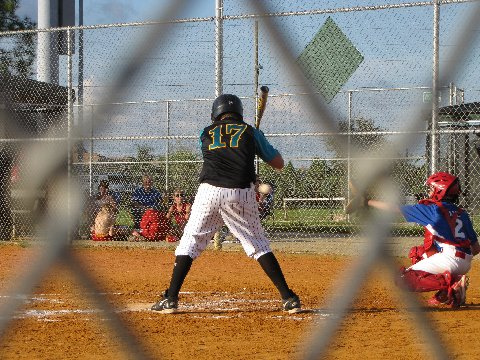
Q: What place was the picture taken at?
A: It was taken at the field.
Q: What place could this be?
A: It is a field.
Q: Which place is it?
A: It is a field.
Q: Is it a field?
A: Yes, it is a field.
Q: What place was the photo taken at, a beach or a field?
A: It was taken at a field.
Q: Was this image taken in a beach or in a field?
A: It was taken at a field.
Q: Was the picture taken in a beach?
A: No, the picture was taken in a field.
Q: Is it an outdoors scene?
A: Yes, it is outdoors.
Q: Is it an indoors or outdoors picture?
A: It is outdoors.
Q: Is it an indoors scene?
A: No, it is outdoors.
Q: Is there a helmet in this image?
A: Yes, there is a helmet.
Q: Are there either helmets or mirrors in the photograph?
A: Yes, there is a helmet.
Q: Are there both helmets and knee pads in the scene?
A: No, there is a helmet but no knee pads.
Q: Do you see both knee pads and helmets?
A: No, there is a helmet but no knee pads.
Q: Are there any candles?
A: No, there are no candles.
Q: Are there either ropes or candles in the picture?
A: No, there are no candles or ropes.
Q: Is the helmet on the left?
A: No, the helmet is on the right of the image.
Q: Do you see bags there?
A: No, there are no bags.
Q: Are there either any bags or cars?
A: No, there are no bags or cars.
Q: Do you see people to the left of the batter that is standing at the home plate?
A: Yes, there is a person to the left of the batter.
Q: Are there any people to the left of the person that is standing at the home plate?
A: Yes, there is a person to the left of the batter.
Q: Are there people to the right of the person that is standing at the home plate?
A: No, the person is to the left of the batter.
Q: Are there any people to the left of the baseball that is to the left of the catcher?
A: Yes, there is a person to the left of the baseball.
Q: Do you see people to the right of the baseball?
A: No, the person is to the left of the baseball.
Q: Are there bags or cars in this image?
A: No, there are no cars or bags.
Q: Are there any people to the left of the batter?
A: Yes, there is a person to the left of the batter.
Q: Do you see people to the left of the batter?
A: Yes, there is a person to the left of the batter.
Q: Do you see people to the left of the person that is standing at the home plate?
A: Yes, there is a person to the left of the batter.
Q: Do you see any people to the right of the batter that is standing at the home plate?
A: No, the person is to the left of the batter.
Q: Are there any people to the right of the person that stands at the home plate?
A: No, the person is to the left of the batter.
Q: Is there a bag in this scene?
A: No, there are no bags.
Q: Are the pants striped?
A: Yes, the pants are striped.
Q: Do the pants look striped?
A: Yes, the pants are striped.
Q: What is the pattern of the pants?
A: The pants are striped.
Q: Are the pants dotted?
A: No, the pants are striped.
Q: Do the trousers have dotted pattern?
A: No, the trousers are striped.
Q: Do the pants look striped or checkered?
A: The pants are striped.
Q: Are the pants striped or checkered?
A: The pants are striped.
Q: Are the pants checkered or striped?
A: The pants are striped.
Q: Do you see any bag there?
A: No, there are no bags.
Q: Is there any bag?
A: No, there are no bags.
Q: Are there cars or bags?
A: No, there are no bags or cars.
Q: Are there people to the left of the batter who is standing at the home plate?
A: Yes, there is a person to the left of the batter.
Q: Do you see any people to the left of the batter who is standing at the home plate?
A: Yes, there is a person to the left of the batter.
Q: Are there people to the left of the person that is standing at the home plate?
A: Yes, there is a person to the left of the batter.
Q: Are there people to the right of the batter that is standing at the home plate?
A: No, the person is to the left of the batter.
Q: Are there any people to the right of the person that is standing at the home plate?
A: No, the person is to the left of the batter.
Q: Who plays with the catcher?
A: The batter plays with the catcher.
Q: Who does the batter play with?
A: The batter plays with the catcher.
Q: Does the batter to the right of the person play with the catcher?
A: Yes, the batter plays with the catcher.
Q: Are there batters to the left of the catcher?
A: Yes, there is a batter to the left of the catcher.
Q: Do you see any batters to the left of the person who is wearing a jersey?
A: Yes, there is a batter to the left of the catcher.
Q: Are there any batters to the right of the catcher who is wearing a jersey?
A: No, the batter is to the left of the catcher.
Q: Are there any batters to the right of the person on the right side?
A: No, the batter is to the left of the catcher.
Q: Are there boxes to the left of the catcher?
A: No, there is a batter to the left of the catcher.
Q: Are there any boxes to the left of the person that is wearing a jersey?
A: No, there is a batter to the left of the catcher.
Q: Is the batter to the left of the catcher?
A: Yes, the batter is to the left of the catcher.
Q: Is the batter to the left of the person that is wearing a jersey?
A: Yes, the batter is to the left of the catcher.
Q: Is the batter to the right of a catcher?
A: No, the batter is to the left of a catcher.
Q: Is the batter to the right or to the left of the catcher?
A: The batter is to the left of the catcher.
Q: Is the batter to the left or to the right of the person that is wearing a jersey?
A: The batter is to the left of the catcher.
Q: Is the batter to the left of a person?
A: No, the batter is to the right of a person.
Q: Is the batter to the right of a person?
A: Yes, the batter is to the right of a person.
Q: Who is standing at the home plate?
A: The batter is standing at the home plate.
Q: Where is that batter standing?
A: The batter is standing at the home plate.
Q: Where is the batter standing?
A: The batter is standing at the home plate.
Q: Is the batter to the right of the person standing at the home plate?
A: Yes, the batter is standing at the home plate.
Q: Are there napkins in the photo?
A: No, there are no napkins.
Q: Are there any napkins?
A: No, there are no napkins.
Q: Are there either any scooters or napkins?
A: No, there are no napkins or scooters.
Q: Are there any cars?
A: No, there are no cars.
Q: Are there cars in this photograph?
A: No, there are no cars.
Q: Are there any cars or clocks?
A: No, there are no cars or clocks.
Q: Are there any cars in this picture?
A: No, there are no cars.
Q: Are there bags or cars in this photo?
A: No, there are no cars or bags.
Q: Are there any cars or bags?
A: No, there are no cars or bags.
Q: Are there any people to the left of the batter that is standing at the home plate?
A: Yes, there is a person to the left of the batter.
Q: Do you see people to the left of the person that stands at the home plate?
A: Yes, there is a person to the left of the batter.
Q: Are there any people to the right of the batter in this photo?
A: No, the person is to the left of the batter.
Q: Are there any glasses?
A: No, there are no glasses.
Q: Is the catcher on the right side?
A: Yes, the catcher is on the right of the image.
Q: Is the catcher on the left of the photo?
A: No, the catcher is on the right of the image.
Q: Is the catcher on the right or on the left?
A: The catcher is on the right of the image.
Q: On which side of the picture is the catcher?
A: The catcher is on the right of the image.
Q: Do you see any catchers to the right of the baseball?
A: Yes, there is a catcher to the right of the baseball.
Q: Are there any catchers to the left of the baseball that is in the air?
A: No, the catcher is to the right of the baseball.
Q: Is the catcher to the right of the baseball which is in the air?
A: Yes, the catcher is to the right of the baseball.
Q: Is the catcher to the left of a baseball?
A: No, the catcher is to the right of a baseball.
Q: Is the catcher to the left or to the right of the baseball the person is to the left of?
A: The catcher is to the right of the baseball.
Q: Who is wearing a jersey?
A: The catcher is wearing a jersey.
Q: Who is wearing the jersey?
A: The catcher is wearing a jersey.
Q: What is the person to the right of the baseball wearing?
A: The catcher is wearing a jersey.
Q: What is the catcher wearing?
A: The catcher is wearing a jersey.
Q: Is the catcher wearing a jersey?
A: Yes, the catcher is wearing a jersey.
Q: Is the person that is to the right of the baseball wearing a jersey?
A: Yes, the catcher is wearing a jersey.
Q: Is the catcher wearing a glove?
A: No, the catcher is wearing a jersey.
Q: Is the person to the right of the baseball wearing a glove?
A: No, the catcher is wearing a jersey.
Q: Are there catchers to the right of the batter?
A: Yes, there is a catcher to the right of the batter.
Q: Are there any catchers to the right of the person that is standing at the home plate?
A: Yes, there is a catcher to the right of the batter.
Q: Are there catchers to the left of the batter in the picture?
A: No, the catcher is to the right of the batter.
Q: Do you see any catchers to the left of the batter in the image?
A: No, the catcher is to the right of the batter.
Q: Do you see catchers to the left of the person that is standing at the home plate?
A: No, the catcher is to the right of the batter.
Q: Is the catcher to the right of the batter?
A: Yes, the catcher is to the right of the batter.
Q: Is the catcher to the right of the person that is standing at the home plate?
A: Yes, the catcher is to the right of the batter.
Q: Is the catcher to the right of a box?
A: No, the catcher is to the right of the batter.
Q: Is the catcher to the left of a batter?
A: No, the catcher is to the right of a batter.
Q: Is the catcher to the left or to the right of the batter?
A: The catcher is to the right of the batter.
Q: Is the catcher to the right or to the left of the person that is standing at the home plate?
A: The catcher is to the right of the batter.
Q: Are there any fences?
A: Yes, there is a fence.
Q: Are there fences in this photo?
A: Yes, there is a fence.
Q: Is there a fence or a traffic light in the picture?
A: Yes, there is a fence.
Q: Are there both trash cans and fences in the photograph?
A: No, there is a fence but no trash cans.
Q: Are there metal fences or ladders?
A: Yes, there is a metal fence.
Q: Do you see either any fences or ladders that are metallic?
A: Yes, the fence is metallic.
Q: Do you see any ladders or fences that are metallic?
A: Yes, the fence is metallic.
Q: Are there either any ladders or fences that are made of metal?
A: Yes, the fence is made of metal.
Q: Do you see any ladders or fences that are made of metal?
A: Yes, the fence is made of metal.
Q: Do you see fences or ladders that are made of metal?
A: Yes, the fence is made of metal.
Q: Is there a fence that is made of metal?
A: Yes, there is a fence that is made of metal.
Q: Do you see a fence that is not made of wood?
A: Yes, there is a fence that is made of metal.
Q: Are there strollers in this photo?
A: No, there are no strollers.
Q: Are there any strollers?
A: No, there are no strollers.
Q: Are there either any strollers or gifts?
A: No, there are no strollers or gifts.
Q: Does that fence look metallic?
A: Yes, the fence is metallic.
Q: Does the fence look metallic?
A: Yes, the fence is metallic.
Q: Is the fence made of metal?
A: Yes, the fence is made of metal.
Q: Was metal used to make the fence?
A: Yes, the fence is made of metal.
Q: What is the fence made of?
A: The fence is made of metal.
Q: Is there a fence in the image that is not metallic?
A: No, there is a fence but it is metallic.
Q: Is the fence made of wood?
A: No, the fence is made of metal.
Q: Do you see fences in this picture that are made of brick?
A: No, there is a fence but it is made of metal.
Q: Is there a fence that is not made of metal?
A: No, there is a fence but it is made of metal.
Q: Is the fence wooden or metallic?
A: The fence is metallic.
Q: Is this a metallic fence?
A: Yes, this is a metallic fence.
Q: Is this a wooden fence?
A: No, this is a metallic fence.